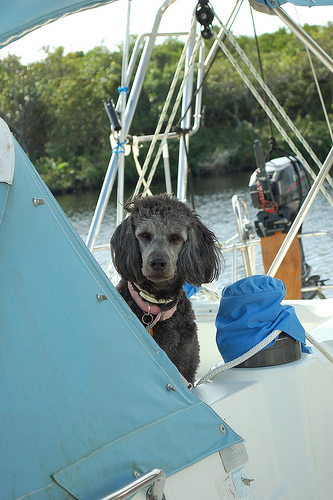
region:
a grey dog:
[102, 188, 228, 393]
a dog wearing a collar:
[122, 199, 203, 318]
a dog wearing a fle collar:
[122, 198, 212, 321]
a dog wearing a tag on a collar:
[123, 200, 211, 359]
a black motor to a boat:
[215, 137, 318, 241]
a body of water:
[65, 165, 265, 245]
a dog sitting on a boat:
[34, 103, 312, 341]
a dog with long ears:
[95, 202, 216, 302]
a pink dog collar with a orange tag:
[133, 283, 191, 341]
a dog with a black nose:
[93, 214, 211, 311]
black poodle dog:
[107, 195, 204, 381]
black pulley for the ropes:
[186, 0, 224, 48]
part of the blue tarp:
[17, 298, 75, 381]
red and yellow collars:
[127, 283, 195, 333]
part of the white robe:
[221, 355, 247, 380]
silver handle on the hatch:
[97, 461, 181, 498]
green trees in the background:
[24, 71, 88, 112]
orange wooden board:
[284, 258, 295, 286]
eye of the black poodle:
[168, 229, 181, 245]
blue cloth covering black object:
[207, 265, 308, 373]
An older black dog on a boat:
[104, 190, 219, 364]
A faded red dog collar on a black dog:
[126, 277, 189, 325]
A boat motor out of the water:
[240, 141, 315, 238]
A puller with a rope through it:
[186, 2, 227, 48]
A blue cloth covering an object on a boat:
[216, 270, 319, 382]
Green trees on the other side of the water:
[38, 72, 93, 172]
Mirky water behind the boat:
[201, 179, 230, 207]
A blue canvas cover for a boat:
[2, 138, 91, 497]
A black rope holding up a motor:
[260, 131, 288, 161]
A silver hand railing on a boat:
[83, 463, 179, 499]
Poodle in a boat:
[106, 191, 227, 386]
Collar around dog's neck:
[123, 282, 182, 327]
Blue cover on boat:
[0, 114, 244, 498]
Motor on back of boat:
[237, 139, 313, 242]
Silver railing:
[99, 468, 164, 499]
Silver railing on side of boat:
[99, 466, 167, 496]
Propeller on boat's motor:
[250, 137, 284, 219]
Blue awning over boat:
[0, 0, 117, 47]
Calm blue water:
[44, 168, 329, 267]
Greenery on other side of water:
[0, 22, 331, 190]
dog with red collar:
[109, 193, 207, 325]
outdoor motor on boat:
[240, 132, 316, 241]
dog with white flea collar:
[105, 189, 212, 319]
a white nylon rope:
[200, 337, 279, 383]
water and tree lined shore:
[199, 137, 244, 190]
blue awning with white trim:
[2, 1, 89, 40]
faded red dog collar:
[122, 279, 188, 332]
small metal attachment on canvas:
[27, 193, 48, 212]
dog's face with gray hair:
[107, 193, 216, 289]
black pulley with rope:
[188, 0, 222, 44]